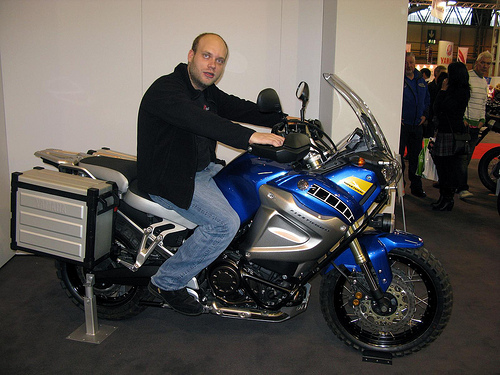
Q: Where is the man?
A: On a blue and silver motorcycle.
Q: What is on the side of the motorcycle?
A: A silver saddle box.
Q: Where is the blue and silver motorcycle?
A: At an exhibition.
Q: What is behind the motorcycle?
A: A wall.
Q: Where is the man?
A: Sitting on a blue and silver motorcycle.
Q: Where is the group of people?
A: Standing in a showroom.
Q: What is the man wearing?
A: Faded blue denim jeans.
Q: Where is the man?
A: Sitting on a motorcycle.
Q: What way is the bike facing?
A: Right.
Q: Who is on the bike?
A: A man in blue jeans.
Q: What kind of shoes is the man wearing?
A: Black tennis shoes.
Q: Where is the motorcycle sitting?
A: On a cement floor.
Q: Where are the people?
A: Inside of a building.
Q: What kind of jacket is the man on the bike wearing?
A: Black jacket.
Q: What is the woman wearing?
A: A plaid skirt.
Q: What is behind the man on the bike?
A: A beige wall.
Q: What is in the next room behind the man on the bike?
A: People standing around.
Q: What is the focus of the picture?
A: Man on a motorcycle.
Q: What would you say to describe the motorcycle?
A: It is blue and silver.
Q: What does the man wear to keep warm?
A: A dark jacket.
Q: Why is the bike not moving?
A: It is parked indoors.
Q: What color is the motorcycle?
A: Blue.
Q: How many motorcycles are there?
A: One.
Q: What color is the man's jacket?
A: Black.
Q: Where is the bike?
A: At a motorcycle event.